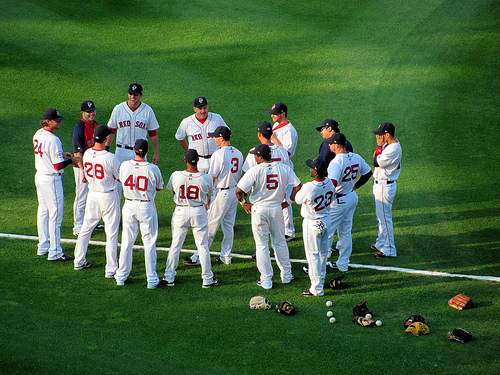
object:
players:
[370, 121, 403, 260]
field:
[0, 0, 500, 82]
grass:
[7, 292, 222, 371]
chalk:
[0, 229, 500, 286]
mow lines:
[372, 0, 500, 268]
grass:
[18, 15, 482, 81]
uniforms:
[165, 170, 215, 285]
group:
[34, 80, 404, 299]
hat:
[266, 101, 288, 116]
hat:
[372, 121, 398, 136]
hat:
[256, 121, 276, 134]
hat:
[182, 147, 200, 161]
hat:
[193, 97, 208, 108]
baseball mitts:
[248, 295, 272, 311]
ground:
[0, 15, 499, 85]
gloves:
[405, 321, 431, 337]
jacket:
[72, 117, 100, 168]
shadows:
[356, 177, 499, 215]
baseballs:
[325, 310, 333, 318]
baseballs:
[323, 298, 335, 308]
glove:
[444, 291, 473, 312]